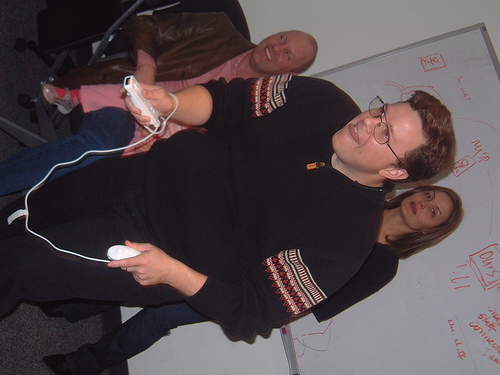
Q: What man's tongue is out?
A: The man playing.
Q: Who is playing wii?
A: The man in front.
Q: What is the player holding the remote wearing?
A: A black sweater.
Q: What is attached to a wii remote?
A: A nunchuck.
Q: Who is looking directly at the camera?
A: The woman in back.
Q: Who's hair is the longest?
A: The woman's brown hair.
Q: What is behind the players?
A: A white board.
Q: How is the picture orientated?
A: On its side.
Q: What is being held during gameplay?
A: The controller.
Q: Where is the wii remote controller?
A: In the man's hands.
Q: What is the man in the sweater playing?
A: Nintendo Wii.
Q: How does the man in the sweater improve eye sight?
A: With eye glasses.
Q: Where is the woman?
A: Behind the man in the sweater.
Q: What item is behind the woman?
A: A dry erase white board.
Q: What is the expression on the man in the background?
A: Smiling happy.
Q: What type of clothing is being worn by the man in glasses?
A: A sweater.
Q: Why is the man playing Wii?
A: For fun.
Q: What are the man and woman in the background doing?
A: Watching the man in the sweater play Wii.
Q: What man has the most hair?
A: The man in the sweater.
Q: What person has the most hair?
A: The woman.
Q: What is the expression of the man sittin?
A: Smiling.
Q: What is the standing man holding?
A: A game controller.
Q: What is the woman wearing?
A: A black oufit.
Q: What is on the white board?
A: Writting.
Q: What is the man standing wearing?
A: Black pants.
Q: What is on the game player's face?
A: Glasses.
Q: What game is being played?
A: Wii.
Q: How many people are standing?
A: 2.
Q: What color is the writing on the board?
A: Red.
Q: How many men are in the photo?
A: 2.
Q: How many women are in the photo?
A: 1.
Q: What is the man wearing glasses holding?
A: A Wii control.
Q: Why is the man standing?
A: Playing a game.